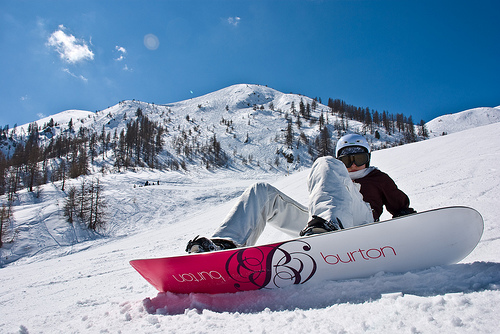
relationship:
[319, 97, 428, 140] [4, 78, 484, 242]
trees on mountain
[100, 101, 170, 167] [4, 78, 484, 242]
trees on mountain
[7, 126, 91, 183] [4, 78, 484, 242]
trees on mountain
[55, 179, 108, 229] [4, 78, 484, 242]
trees on mountain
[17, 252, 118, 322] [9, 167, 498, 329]
snow on ground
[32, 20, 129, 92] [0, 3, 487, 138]
cloud in sky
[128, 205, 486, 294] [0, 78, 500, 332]
snow boarding in snow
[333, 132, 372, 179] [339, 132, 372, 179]
helmet on head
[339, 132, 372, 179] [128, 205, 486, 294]
head on snow boarding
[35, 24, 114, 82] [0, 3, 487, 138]
cloud in sky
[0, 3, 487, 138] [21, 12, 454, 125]
sky in distance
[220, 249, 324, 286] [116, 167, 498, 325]
design on a snowboard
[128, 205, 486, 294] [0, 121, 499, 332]
snow boarding in snow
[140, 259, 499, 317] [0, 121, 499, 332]
shadow in snow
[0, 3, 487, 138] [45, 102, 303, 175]
sky above land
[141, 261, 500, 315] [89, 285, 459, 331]
shadow on ground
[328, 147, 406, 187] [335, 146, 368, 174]
goggles on face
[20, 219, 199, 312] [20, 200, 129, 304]
snow on ground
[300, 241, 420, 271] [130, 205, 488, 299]
writing on board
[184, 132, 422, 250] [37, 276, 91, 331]
man sitting in snow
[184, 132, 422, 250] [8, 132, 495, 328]
man on hill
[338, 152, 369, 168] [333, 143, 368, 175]
goggles are on face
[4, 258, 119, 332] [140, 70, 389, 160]
snow on mountain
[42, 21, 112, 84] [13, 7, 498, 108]
cloud in sky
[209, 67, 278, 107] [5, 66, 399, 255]
top on mountain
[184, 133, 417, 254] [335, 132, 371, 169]
man has head